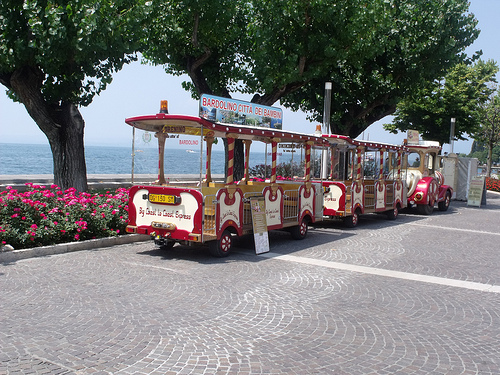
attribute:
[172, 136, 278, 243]
train — white, parked, red, tan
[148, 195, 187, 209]
plate — yellow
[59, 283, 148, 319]
ground — stone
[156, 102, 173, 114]
light — orange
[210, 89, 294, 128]
sign — long, language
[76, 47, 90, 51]
leaves — green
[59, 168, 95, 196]
trunk — large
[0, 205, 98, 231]
bushes — red, pink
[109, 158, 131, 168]
water — calm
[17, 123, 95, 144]
tree — green, small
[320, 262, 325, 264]
line — white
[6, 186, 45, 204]
flowers — pink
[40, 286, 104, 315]
bricks — tan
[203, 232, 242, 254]
tire — red